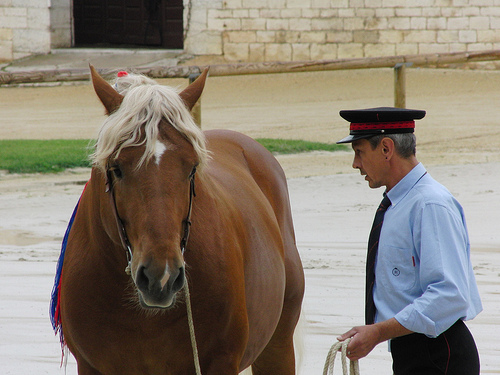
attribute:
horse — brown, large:
[44, 59, 315, 372]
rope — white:
[324, 334, 357, 374]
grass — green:
[0, 132, 349, 172]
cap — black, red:
[333, 105, 430, 146]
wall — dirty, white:
[181, 1, 499, 61]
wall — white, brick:
[3, 0, 497, 70]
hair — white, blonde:
[89, 70, 210, 189]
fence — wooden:
[1, 50, 499, 148]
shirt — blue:
[349, 163, 483, 346]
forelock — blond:
[83, 84, 211, 171]